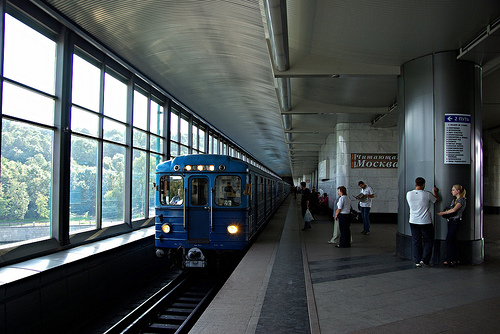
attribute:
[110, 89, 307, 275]
train — blue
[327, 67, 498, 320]
hallway — long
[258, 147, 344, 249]
tunnels — white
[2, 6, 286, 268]
window — long, clear, glass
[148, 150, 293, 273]
train — blue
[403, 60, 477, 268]
pillar — large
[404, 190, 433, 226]
shirt — white